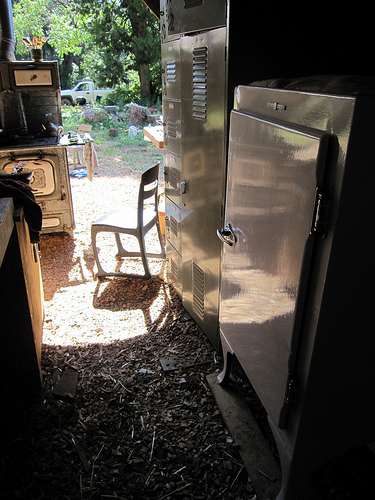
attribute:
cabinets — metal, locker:
[156, 41, 194, 311]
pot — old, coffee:
[23, 105, 56, 141]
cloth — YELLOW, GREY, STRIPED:
[80, 135, 97, 179]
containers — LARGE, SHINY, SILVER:
[157, 22, 349, 476]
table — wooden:
[56, 129, 102, 182]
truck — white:
[59, 79, 116, 109]